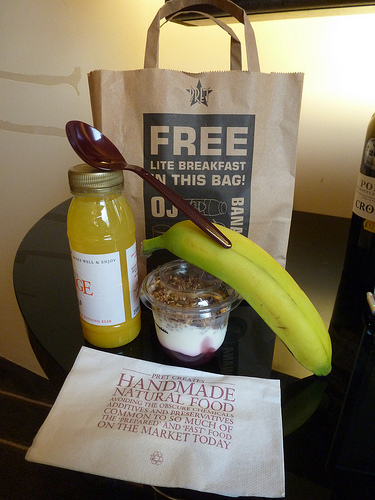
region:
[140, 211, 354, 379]
Whole ripe banana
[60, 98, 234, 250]
Brown plastic spoon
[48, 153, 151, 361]
Unopened bottle of orange juice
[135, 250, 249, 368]
Fruit and nut yogurt parfait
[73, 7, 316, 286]
Brown paper bag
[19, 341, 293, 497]
White paper napkin with red print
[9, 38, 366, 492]
This is the free lite breakfast from the sack.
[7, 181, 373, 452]
Food is on the table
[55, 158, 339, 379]
Juice, parfait, and banana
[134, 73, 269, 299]
The black print on the paper bag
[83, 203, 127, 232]
yellow liquid in glass bottle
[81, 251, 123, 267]
black words on white label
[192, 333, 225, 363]
fruits in parfait cup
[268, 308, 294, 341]
spots on yellow banana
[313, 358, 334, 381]
edge of yellow banana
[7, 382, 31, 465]
white lines on the black floor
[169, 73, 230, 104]
black star on paper bag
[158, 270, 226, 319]
granola in yogurt cup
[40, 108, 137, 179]
black shiny spoon on yogurt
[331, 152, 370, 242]
edge of wine bottle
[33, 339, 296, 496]
A napkin.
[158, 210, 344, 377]
A banana that is not completely ripe.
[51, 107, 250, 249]
A brown spoon.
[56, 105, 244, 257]
The spoon is made from plastic.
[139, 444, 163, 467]
The recycling symbol on the napkin.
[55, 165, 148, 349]
A bottle of orange juice.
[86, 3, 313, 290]
A large paper bag.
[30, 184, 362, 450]
The food is on a counter.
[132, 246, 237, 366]
A breakfast parfait.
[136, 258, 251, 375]
The parfait is in a plastic container.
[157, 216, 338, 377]
Yellow and green banana balanced on yogurt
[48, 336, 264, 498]
White napkin with red printed words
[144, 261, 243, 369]
Plastic container of yogurt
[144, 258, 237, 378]
Plastic container of yogurt parfait with nuts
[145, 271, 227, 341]
Chopped nuts on yogurt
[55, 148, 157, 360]
Bottle of orange juice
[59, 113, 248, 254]
Red spoon balanced on juice bottle and banana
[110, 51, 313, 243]
Brown and black paper bag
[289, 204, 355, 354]
Black table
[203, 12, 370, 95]
Reflection of light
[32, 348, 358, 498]
large white paper on table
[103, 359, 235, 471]
bold red words on paper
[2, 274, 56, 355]
edge of black round table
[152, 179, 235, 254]
edge of black spoon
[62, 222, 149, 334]
white label on orange juice bottle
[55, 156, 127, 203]
gold label on bottle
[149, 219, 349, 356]
large yellow banana on yogurt top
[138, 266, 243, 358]
cup of yogurt with granola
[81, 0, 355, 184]
large brown plastic bag with handle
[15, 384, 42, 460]
white lines on floor